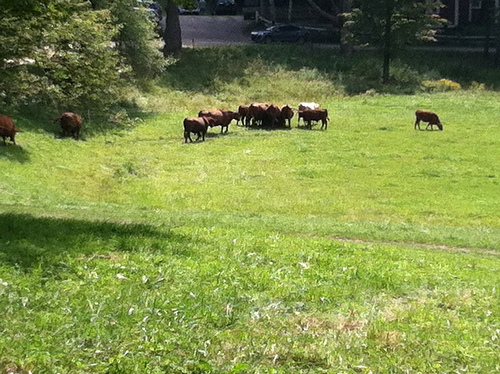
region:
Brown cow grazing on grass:
[412, 105, 447, 135]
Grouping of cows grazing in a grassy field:
[176, 96, 334, 151]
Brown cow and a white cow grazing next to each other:
[294, 95, 332, 129]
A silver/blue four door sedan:
[246, 18, 316, 47]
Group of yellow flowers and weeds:
[421, 69, 462, 93]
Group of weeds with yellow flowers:
[420, 73, 462, 94]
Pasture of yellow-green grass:
[119, 148, 496, 333]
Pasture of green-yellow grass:
[161, 178, 467, 338]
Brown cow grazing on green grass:
[391, 94, 480, 144]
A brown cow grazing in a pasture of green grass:
[409, 104, 474, 139]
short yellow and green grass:
[37, 271, 132, 297]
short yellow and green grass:
[147, 241, 215, 288]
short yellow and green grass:
[283, 282, 333, 315]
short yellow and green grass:
[355, 249, 461, 361]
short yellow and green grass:
[212, 217, 291, 253]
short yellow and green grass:
[99, 182, 167, 250]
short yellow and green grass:
[318, 176, 389, 244]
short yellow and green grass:
[143, 148, 309, 205]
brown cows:
[188, 90, 300, 150]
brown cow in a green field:
[411, 103, 445, 135]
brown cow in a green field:
[1, 113, 21, 143]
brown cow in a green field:
[53, 108, 88, 142]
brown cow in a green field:
[182, 113, 218, 148]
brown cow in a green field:
[192, 105, 236, 136]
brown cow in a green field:
[293, 103, 335, 133]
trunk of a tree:
[375, 30, 398, 87]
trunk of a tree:
[157, 0, 196, 52]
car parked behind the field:
[245, 15, 316, 50]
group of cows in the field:
[177, 86, 335, 148]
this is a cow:
[392, 90, 461, 150]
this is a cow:
[292, 103, 339, 137]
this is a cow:
[294, 86, 325, 126]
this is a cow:
[272, 100, 310, 130]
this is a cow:
[259, 92, 289, 132]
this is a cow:
[238, 90, 275, 132]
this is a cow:
[202, 94, 244, 139]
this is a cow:
[164, 116, 223, 156]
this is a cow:
[52, 95, 97, 148]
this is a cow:
[0, 112, 25, 158]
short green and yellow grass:
[32, 154, 100, 195]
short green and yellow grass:
[258, 167, 299, 230]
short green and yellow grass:
[364, 218, 406, 275]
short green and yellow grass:
[134, 173, 160, 203]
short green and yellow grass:
[153, 230, 221, 282]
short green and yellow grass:
[28, 200, 97, 250]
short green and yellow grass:
[101, 240, 177, 298]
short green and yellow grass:
[42, 264, 100, 313]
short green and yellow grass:
[182, 261, 250, 327]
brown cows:
[169, 94, 269, 138]